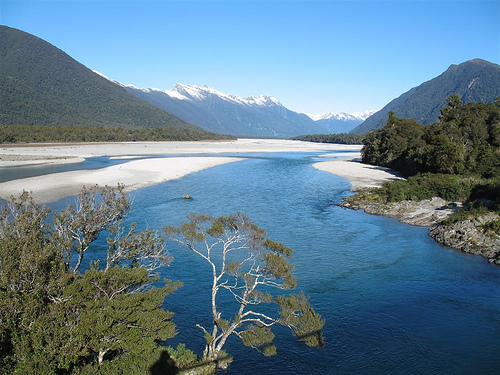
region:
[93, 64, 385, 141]
Mountain peaks covered with snow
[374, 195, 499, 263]
Shore line covered with rocks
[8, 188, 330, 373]
Tree with pale branches and green needles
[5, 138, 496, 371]
Water with ice on it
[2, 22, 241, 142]
Moutain covered with trees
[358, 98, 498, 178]
Large group of tall green trees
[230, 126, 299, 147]
Gap between moutains covered with ice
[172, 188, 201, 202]
Small rock in blue water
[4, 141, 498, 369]
Blue river with small waves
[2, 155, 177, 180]
Water running through two sides of ice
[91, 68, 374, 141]
snow covered mountain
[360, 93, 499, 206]
dark green colored trees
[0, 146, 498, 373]
bright blue colored water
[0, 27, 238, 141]
a hill covered with green vegetation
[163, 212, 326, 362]
a tree branch that is gray in color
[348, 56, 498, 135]
a high hill top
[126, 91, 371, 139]
shadows on the side of the mountain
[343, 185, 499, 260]
a rocky part of the shore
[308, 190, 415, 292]
waves in the water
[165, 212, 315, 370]
green tree by the sandy river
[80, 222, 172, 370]
green tree by the sandy river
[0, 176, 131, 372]
green tree by the sandy river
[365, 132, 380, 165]
green tree by the sandy river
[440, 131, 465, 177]
green tree by the sandy river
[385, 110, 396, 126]
green tree by the sandy river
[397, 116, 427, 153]
green tree by the sandy river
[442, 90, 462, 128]
green tree by the sandy river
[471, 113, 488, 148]
green tree by the sandy river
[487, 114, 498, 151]
green tree by the sandy river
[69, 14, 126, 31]
white clouds in blue sky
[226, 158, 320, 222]
calm blue lake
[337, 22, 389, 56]
white clouds in blue sky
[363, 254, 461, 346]
Large body of water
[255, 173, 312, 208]
Large body of water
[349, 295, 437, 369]
Large body of water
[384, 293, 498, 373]
Large body of water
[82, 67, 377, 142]
snow capped mountains in the distance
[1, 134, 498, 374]
the river is running at a low level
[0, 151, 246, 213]
an island in the river bead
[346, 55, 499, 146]
this mountain is pyramid shapped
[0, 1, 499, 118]
the sky is clear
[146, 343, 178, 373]
the photographer's shadow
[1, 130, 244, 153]
the normal lake shore on the left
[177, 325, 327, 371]
a fence shadow is seen on the tree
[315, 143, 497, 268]
the right bank of the river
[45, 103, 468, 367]
a body of water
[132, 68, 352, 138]
mountains in the distance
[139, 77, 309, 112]
snow on the mountains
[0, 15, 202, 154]
mountain on the side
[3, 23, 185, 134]
greenery on the mountain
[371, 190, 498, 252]
rocks next to the water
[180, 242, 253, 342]
limbs of the tree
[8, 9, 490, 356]
a bright and sunny day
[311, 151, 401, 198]
shore of beach by trees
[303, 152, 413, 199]
shore of beach by trees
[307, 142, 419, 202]
shore of beach by trees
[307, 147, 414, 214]
shore of beach by trees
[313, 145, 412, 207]
shore of beach by trees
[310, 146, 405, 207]
shore of beach by trees